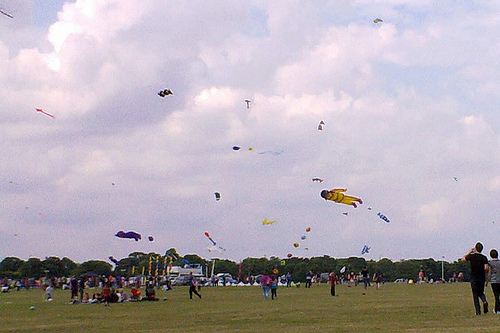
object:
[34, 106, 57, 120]
kite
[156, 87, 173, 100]
kite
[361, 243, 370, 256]
kite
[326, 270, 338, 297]
man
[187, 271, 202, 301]
man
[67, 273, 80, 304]
man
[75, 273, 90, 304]
man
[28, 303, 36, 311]
ball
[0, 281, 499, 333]
ground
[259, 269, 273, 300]
people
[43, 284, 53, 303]
people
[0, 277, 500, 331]
grass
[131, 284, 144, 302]
people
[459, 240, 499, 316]
couple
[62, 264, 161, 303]
group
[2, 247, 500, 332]
park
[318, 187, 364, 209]
kite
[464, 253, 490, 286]
shirt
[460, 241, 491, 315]
guy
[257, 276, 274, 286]
shirt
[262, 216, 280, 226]
kite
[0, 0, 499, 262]
sky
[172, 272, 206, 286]
vehicles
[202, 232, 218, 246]
kite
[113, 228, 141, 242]
kite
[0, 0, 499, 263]
clouds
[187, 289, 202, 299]
pants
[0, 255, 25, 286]
tree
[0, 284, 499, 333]
field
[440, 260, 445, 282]
pole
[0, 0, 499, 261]
cloudy